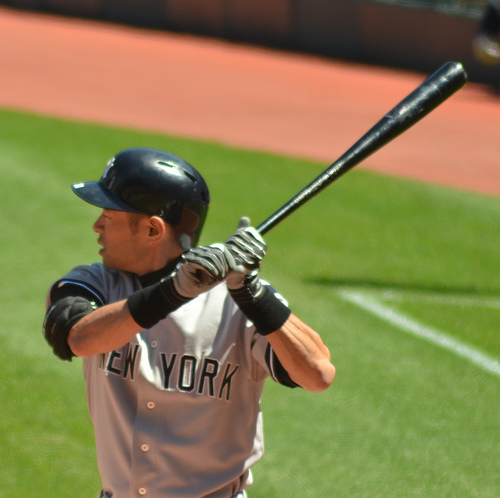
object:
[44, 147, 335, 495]
player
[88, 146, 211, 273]
head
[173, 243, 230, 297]
gloves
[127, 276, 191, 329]
sweatband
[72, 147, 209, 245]
helmet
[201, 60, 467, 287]
bat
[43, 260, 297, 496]
outfit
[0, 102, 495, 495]
field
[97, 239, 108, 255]
mouth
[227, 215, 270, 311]
hand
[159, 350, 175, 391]
letters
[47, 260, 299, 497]
shirt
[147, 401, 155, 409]
buttons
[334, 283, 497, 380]
line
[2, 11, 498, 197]
dirt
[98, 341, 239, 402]
embriodery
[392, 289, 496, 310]
lines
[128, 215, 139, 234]
sideburns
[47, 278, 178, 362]
arm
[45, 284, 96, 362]
brace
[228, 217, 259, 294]
glove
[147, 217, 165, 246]
ear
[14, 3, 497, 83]
pad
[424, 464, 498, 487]
grass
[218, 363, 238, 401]
letter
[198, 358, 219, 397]
letter